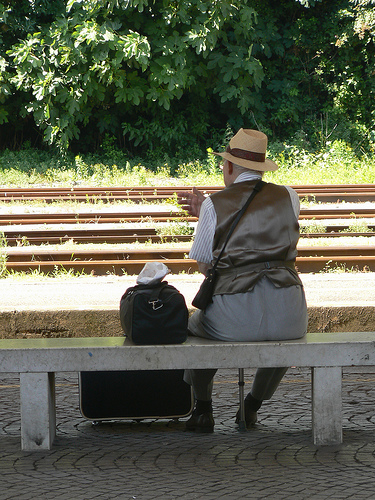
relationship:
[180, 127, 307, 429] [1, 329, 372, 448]
man on bench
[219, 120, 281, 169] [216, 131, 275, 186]
hat on person's head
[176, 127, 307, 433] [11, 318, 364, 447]
man on bench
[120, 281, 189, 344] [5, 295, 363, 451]
bag on bench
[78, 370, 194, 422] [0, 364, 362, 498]
bag on ground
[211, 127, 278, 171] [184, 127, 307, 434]
hat on a person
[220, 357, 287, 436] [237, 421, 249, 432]
cane with a tip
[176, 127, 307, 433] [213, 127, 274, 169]
man wearing a hat